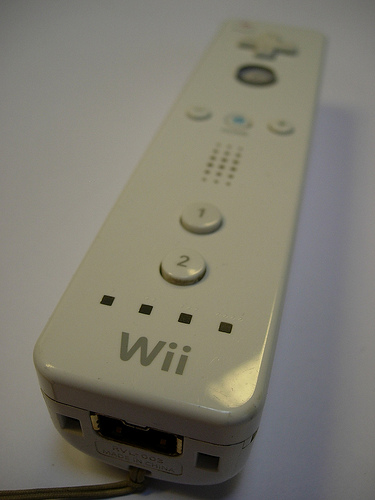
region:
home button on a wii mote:
[225, 109, 251, 133]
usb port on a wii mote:
[89, 404, 189, 464]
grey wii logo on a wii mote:
[118, 327, 196, 383]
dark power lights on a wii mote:
[99, 289, 238, 340]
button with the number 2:
[160, 242, 206, 289]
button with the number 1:
[171, 191, 232, 237]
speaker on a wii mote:
[202, 145, 241, 183]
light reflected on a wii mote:
[204, 371, 268, 421]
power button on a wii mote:
[233, 17, 252, 33]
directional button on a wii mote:
[237, 25, 302, 68]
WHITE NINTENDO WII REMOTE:
[62, 46, 320, 421]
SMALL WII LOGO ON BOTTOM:
[97, 309, 198, 396]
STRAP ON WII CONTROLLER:
[17, 446, 117, 498]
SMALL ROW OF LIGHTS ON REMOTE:
[89, 285, 252, 343]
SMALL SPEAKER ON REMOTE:
[193, 131, 247, 182]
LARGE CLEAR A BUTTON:
[236, 51, 268, 88]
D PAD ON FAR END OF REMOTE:
[245, 25, 297, 64]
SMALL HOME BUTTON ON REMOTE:
[239, 105, 253, 134]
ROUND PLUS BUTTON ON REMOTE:
[263, 116, 293, 141]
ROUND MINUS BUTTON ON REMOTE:
[186, 94, 219, 120]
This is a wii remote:
[13, 179, 300, 477]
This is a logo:
[112, 342, 219, 387]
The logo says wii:
[115, 338, 188, 400]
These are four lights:
[53, 227, 274, 344]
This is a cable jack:
[54, 352, 264, 468]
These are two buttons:
[156, 183, 275, 343]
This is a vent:
[193, 120, 261, 193]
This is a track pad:
[236, 32, 344, 60]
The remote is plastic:
[155, 341, 315, 454]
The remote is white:
[123, 300, 248, 456]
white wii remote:
[35, 15, 331, 485]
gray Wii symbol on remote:
[116, 327, 192, 379]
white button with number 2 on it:
[159, 249, 207, 286]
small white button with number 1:
[177, 201, 222, 234]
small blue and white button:
[227, 110, 250, 129]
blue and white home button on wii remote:
[223, 106, 254, 127]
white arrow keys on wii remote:
[231, 26, 298, 61]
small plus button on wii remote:
[271, 117, 297, 137]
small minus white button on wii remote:
[181, 99, 212, 121]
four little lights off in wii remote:
[98, 291, 234, 338]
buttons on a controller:
[149, 189, 232, 291]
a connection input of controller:
[77, 404, 191, 465]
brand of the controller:
[109, 326, 204, 379]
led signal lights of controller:
[93, 288, 236, 342]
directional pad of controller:
[234, 26, 303, 61]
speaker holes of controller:
[191, 136, 249, 186]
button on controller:
[228, 58, 281, 88]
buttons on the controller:
[182, 93, 303, 135]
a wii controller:
[19, 10, 334, 495]